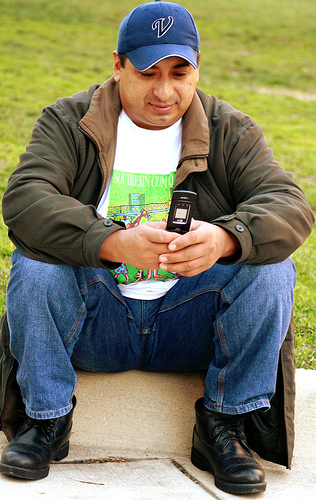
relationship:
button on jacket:
[234, 223, 244, 233] [24, 60, 311, 284]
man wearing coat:
[0, 0, 314, 494] [0, 74, 315, 470]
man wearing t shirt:
[0, 0, 314, 494] [98, 107, 183, 299]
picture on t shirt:
[105, 169, 176, 283] [98, 107, 183, 299]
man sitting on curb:
[0, 0, 314, 494] [67, 366, 315, 471]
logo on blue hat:
[149, 14, 174, 38] [115, 0, 200, 75]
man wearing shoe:
[0, 0, 314, 494] [0, 396, 76, 481]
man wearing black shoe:
[0, 0, 314, 494] [190, 396, 266, 496]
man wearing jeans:
[0, 0, 314, 494] [5, 247, 299, 420]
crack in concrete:
[66, 449, 226, 498] [0, 441, 315, 499]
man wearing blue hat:
[0, 0, 314, 494] [115, 0, 200, 75]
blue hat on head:
[115, 0, 200, 75] [110, 2, 201, 126]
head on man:
[110, 2, 201, 126] [0, 0, 314, 494]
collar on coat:
[76, 76, 211, 186] [0, 74, 315, 470]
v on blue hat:
[148, 15, 175, 38] [115, 0, 200, 75]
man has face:
[0, 0, 314, 494] [119, 57, 194, 127]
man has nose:
[0, 0, 314, 494] [156, 73, 172, 103]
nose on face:
[156, 73, 172, 103] [119, 57, 194, 127]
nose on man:
[156, 73, 172, 103] [0, 0, 314, 494]